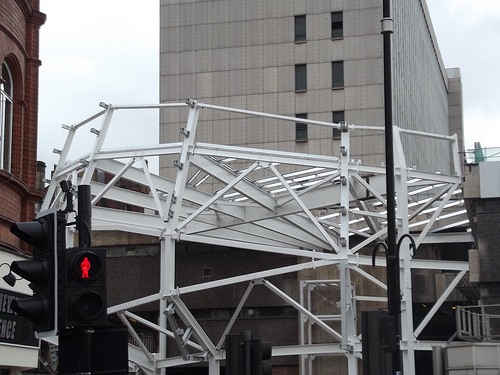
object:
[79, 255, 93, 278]
person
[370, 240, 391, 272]
hooks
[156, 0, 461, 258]
building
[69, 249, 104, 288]
signal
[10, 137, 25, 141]
brick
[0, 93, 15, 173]
window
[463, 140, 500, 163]
fence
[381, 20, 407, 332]
pole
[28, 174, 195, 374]
crosswalk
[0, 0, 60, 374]
building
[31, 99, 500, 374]
scaffolding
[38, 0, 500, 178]
sky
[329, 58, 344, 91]
windows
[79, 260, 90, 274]
red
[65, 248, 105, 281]
light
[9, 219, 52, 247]
signals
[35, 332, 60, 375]
lights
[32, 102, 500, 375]
structure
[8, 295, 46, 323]
sign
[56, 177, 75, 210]
camera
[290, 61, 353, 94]
rows